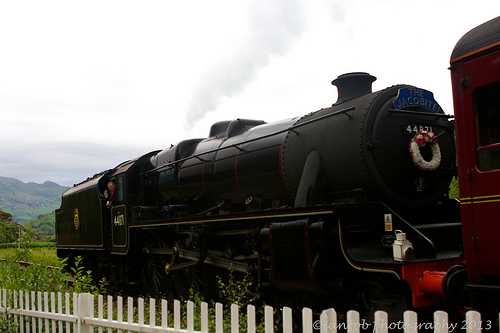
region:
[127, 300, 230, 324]
a white fence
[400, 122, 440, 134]
numbers on the train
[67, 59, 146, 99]
clouds in the sky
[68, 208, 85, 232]
a logo on the train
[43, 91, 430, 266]
old black train engine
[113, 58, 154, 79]
white clouds in blue sky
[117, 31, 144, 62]
white clouds in blue sky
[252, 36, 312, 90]
white clouds in blue sky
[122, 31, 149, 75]
white clouds in blue sky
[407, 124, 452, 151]
red flowers on the circle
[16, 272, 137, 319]
small white picket fence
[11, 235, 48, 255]
lush green landscape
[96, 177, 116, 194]
man leaning out of train car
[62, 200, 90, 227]
gold symbol on side of car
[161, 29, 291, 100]
smoke in the air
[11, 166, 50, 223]
huge mountain range in the back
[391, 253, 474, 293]
orange brakes between train cars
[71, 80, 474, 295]
black train engine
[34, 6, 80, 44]
white clouds in blue sky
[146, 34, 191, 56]
white clouds in blue sky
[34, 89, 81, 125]
white clouds in blue sky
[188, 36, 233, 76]
white clouds in blue sky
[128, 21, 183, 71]
white clouds in blue sky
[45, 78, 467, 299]
black train engine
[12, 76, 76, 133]
white clouds in blue sky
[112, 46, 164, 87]
white clouds in blue sky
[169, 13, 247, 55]
white clouds in blue sky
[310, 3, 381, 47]
white clouds in blue sky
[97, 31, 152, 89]
white clouds in blue sky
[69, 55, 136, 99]
white clouds in blue sky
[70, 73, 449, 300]
black train engine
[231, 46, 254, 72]
white clouds in blue sky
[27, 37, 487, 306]
black train on tracks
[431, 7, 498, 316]
red train car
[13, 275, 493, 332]
white picked fence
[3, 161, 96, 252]
mountain in the background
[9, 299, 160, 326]
white fence on the grass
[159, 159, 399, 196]
Long boiler wagon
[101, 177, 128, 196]
man inside the cabin driving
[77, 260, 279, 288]
black line train wheels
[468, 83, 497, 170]
train carriage window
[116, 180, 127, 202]
train carriage drive window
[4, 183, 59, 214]
green mountains away from the train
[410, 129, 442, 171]
wreath on front of train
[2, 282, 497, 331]
white picket fence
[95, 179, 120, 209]
person looking out window of train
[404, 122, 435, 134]
white numbers on train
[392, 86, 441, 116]
blue sign on train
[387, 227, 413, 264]
white train lantern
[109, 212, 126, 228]
white numbers on side of train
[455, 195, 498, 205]
yellow stripe on train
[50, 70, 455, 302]
black train with person on it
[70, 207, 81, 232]
sign on side of train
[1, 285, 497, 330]
picket fence is white